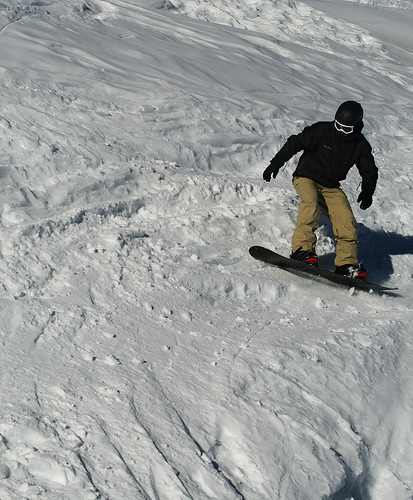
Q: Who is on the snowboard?
A: The man.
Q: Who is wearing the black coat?
A: The man.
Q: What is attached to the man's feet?
A: The snowboard.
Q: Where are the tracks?
A: In the snow.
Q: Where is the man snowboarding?
A: Down the hill.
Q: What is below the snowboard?
A: Snow.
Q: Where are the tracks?
A: In the snow.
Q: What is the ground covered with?
A: Snow.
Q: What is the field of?
A: Snow.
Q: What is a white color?
A: Snow.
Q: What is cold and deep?
A: Snow.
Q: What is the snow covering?
A: A slope.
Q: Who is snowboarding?
A: A man.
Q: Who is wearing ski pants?
A: A man.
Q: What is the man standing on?
A: A black snowboard.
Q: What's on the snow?
A: Tracks.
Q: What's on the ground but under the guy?
A: A black snowboard.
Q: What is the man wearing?
A: Black jacket.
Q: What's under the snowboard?
A: Snow.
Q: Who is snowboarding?
A: The guy.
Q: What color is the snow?
A: White.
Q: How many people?
A: 1.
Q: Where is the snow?
A: On the ground.